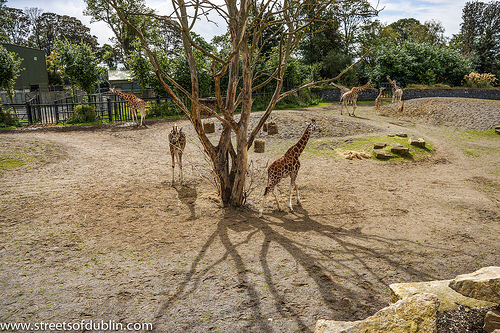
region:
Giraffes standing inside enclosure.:
[258, 72, 416, 212]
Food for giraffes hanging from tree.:
[248, 111, 281, 158]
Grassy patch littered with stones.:
[325, 119, 443, 179]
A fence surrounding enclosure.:
[11, 96, 126, 126]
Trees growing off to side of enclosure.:
[365, 26, 499, 93]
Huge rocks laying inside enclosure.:
[311, 248, 496, 332]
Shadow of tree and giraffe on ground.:
[176, 213, 488, 322]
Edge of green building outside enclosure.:
[2, 40, 60, 122]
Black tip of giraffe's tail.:
[255, 182, 282, 205]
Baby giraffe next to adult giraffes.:
[368, 81, 393, 116]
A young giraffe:
[156, 120, 190, 197]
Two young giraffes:
[155, 117, 326, 221]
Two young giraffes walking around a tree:
[152, 0, 337, 237]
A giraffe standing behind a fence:
[28, 63, 183, 123]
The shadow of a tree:
[158, 213, 450, 331]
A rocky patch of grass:
[348, 128, 436, 165]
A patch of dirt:
[17, 169, 134, 330]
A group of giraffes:
[328, 56, 425, 126]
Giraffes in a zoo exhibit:
[8, 13, 499, 320]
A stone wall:
[410, 82, 499, 106]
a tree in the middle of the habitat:
[97, 3, 383, 233]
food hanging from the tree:
[245, 114, 280, 151]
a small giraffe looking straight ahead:
[156, 121, 191, 192]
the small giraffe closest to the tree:
[262, 116, 327, 218]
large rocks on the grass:
[361, 128, 431, 161]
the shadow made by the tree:
[185, 221, 410, 331]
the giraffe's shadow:
[157, 183, 199, 227]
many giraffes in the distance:
[322, 65, 407, 126]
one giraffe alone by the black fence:
[95, 81, 155, 140]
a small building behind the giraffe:
[100, 63, 158, 102]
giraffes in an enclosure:
[72, 29, 484, 276]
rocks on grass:
[358, 122, 458, 172]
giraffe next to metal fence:
[26, 75, 303, 130]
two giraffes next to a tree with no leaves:
[134, 26, 340, 228]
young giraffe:
[269, 109, 330, 251]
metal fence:
[5, 95, 123, 126]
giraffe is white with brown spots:
[267, 105, 372, 215]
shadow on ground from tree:
[182, 200, 472, 323]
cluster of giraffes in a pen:
[311, 57, 441, 151]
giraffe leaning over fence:
[82, 74, 167, 137]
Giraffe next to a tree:
[236, 114, 332, 224]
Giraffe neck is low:
[160, 111, 197, 213]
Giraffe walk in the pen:
[322, 65, 378, 121]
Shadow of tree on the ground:
[147, 218, 416, 325]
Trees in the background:
[1, 1, 498, 86]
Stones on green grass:
[365, 126, 429, 172]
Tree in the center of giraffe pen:
[110, 0, 379, 221]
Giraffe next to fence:
[88, 76, 160, 131]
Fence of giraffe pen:
[5, 91, 120, 131]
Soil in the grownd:
[6, 207, 353, 325]